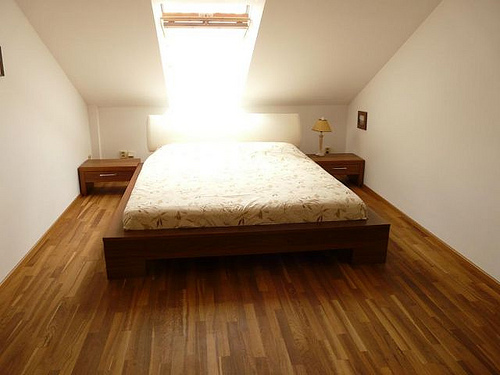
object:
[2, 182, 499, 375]
floor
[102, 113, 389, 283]
bed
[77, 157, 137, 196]
nightstand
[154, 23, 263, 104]
skylight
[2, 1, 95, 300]
wall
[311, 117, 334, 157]
lamp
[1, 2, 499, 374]
bedroom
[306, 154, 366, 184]
nightstand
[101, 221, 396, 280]
footboard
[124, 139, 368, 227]
bedspread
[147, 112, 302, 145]
headboard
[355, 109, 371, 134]
picture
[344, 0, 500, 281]
wall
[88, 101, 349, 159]
wall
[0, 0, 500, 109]
ceiling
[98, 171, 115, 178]
handle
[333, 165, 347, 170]
handle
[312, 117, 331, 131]
shade